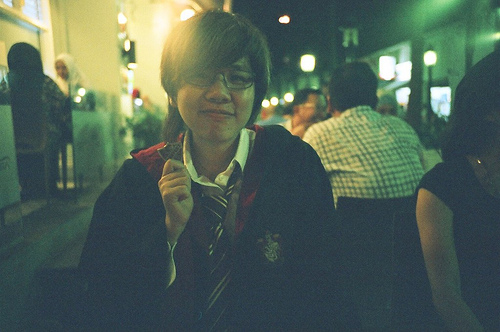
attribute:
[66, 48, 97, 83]
scarf — white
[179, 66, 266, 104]
glasses — black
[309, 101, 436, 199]
shirt — checkered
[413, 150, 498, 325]
shirt — black, crew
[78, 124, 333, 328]
jacket — black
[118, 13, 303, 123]
hair — brown, short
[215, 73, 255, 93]
eye — brown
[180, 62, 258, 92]
glasses — black frame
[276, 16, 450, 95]
street lights — multiple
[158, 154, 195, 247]
woman hand — young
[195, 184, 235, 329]
tie — black, white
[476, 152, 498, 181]
necklace — metal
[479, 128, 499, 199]
neck — woman's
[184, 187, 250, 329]
tie — striped, black, white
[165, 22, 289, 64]
hair — short, black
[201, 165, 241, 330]
tie — black 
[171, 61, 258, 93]
eye glasses — black